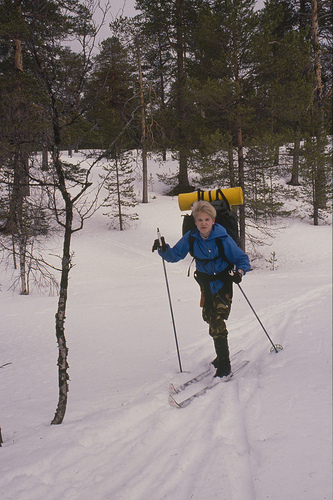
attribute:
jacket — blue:
[158, 226, 249, 292]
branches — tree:
[12, 261, 63, 299]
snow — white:
[278, 229, 331, 317]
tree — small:
[108, 152, 128, 225]